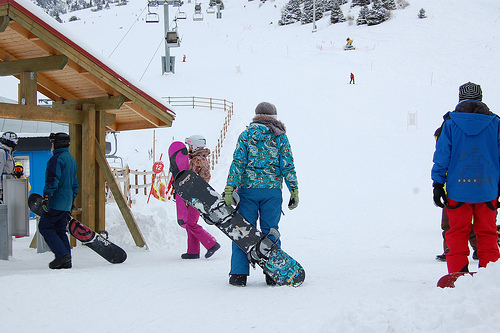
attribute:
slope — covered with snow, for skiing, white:
[8, 6, 494, 327]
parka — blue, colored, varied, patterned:
[226, 114, 298, 195]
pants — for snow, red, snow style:
[444, 194, 498, 276]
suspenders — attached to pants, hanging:
[442, 196, 497, 210]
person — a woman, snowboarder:
[222, 102, 298, 286]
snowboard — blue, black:
[173, 170, 306, 285]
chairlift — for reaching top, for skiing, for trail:
[106, 3, 227, 83]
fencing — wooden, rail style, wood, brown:
[106, 95, 235, 198]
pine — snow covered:
[363, 7, 388, 25]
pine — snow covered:
[332, 6, 345, 24]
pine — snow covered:
[416, 6, 426, 19]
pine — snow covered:
[278, 4, 301, 25]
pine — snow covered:
[302, 4, 322, 24]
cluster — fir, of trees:
[278, 4, 426, 28]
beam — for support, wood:
[3, 54, 68, 77]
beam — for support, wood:
[35, 95, 126, 109]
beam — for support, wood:
[3, 103, 116, 126]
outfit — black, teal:
[226, 116, 298, 276]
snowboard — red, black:
[28, 192, 127, 264]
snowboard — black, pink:
[169, 141, 190, 227]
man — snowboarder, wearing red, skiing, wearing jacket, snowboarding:
[347, 69, 356, 86]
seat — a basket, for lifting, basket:
[163, 31, 179, 45]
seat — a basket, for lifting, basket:
[144, 12, 160, 25]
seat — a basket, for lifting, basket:
[174, 10, 188, 21]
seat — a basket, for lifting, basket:
[191, 9, 205, 22]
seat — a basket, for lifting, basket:
[105, 127, 125, 187]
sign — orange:
[145, 152, 165, 205]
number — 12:
[151, 161, 163, 173]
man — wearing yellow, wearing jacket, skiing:
[342, 36, 357, 52]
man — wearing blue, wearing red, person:
[432, 83, 498, 288]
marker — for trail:
[405, 109, 418, 129]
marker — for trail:
[233, 61, 243, 77]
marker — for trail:
[312, 40, 325, 52]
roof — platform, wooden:
[3, 7, 175, 133]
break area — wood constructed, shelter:
[3, 120, 174, 271]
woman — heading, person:
[181, 133, 221, 259]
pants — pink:
[182, 201, 218, 253]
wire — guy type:
[135, 2, 184, 93]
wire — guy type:
[102, 4, 150, 66]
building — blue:
[3, 133, 54, 220]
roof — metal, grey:
[3, 136, 111, 153]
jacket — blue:
[431, 101, 497, 203]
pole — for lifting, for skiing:
[162, 0, 175, 74]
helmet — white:
[186, 134, 206, 151]